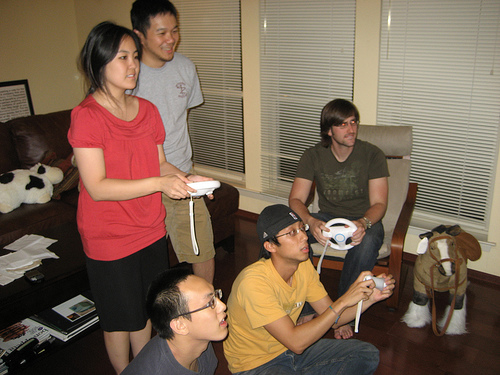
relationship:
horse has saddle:
[400, 225, 467, 335] [453, 227, 480, 262]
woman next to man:
[66, 22, 216, 374] [130, 1, 215, 287]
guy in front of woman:
[220, 204, 395, 375] [66, 22, 216, 374]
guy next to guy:
[220, 204, 395, 375] [124, 263, 231, 375]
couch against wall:
[1, 106, 239, 256] [2, 1, 87, 116]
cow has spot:
[0, 162, 64, 214] [25, 172, 45, 191]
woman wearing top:
[66, 22, 216, 374] [65, 96, 167, 263]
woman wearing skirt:
[66, 22, 216, 374] [84, 236, 171, 333]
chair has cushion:
[304, 123, 419, 313] [311, 124, 413, 259]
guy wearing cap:
[220, 204, 395, 375] [258, 202, 302, 243]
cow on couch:
[0, 162, 64, 214] [1, 106, 239, 256]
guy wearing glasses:
[124, 263, 231, 375] [171, 287, 225, 319]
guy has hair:
[124, 263, 231, 375] [146, 265, 192, 339]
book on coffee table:
[27, 292, 97, 333] [1, 218, 106, 373]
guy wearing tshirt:
[220, 204, 395, 375] [220, 256, 329, 373]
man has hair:
[282, 99, 388, 305] [319, 99, 359, 150]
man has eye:
[282, 99, 388, 305] [348, 118, 355, 124]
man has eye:
[282, 99, 388, 305] [338, 119, 349, 128]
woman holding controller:
[66, 22, 216, 374] [178, 179, 220, 255]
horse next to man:
[400, 225, 467, 335] [282, 99, 388, 305]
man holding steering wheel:
[282, 99, 388, 305] [314, 216, 357, 274]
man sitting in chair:
[282, 99, 388, 305] [304, 123, 419, 313]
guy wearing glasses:
[220, 204, 395, 375] [269, 223, 309, 240]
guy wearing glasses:
[220, 204, 395, 375] [171, 287, 225, 319]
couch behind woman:
[1, 106, 239, 256] [66, 22, 216, 374]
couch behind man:
[1, 106, 239, 256] [130, 1, 215, 287]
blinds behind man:
[259, 0, 355, 214] [282, 99, 388, 305]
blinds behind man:
[171, 0, 243, 182] [130, 1, 215, 287]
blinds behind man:
[377, 1, 498, 243] [282, 99, 388, 305]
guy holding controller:
[220, 204, 395, 375] [353, 276, 389, 333]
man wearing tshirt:
[130, 1, 215, 287] [124, 49, 206, 173]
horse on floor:
[400, 225, 467, 335] [34, 208, 498, 375]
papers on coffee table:
[0, 232, 60, 284] [1, 218, 106, 373]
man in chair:
[282, 99, 388, 305] [304, 123, 419, 313]